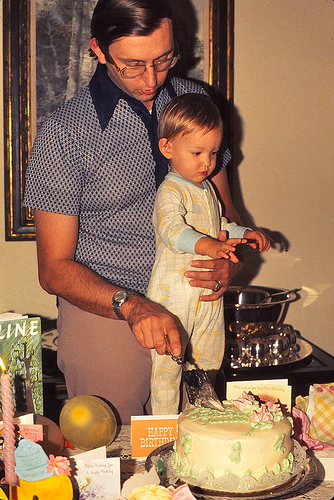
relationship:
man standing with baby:
[21, 0, 241, 425] [144, 92, 272, 416]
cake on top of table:
[172, 391, 295, 491] [55, 424, 333, 499]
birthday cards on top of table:
[68, 378, 292, 499] [55, 424, 333, 499]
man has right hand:
[21, 0, 241, 425] [126, 298, 181, 361]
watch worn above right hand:
[110, 288, 142, 321] [126, 298, 181, 361]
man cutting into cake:
[21, 0, 241, 425] [172, 391, 295, 491]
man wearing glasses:
[21, 0, 241, 425] [105, 35, 182, 78]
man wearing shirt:
[21, 0, 241, 425] [21, 60, 233, 297]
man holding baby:
[21, 0, 241, 425] [144, 92, 272, 416]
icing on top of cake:
[195, 402, 247, 425] [172, 391, 295, 491]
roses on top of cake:
[230, 391, 283, 431] [172, 391, 295, 491]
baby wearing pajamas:
[144, 92, 272, 416] [144, 171, 251, 415]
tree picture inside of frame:
[33, 1, 207, 148] [4, 0, 236, 242]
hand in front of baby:
[185, 255, 241, 302] [144, 92, 272, 416]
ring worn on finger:
[210, 279, 222, 292] [187, 278, 225, 292]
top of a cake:
[179, 390, 292, 441] [172, 391, 295, 491]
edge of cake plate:
[141, 437, 319, 499] [146, 437, 319, 499]